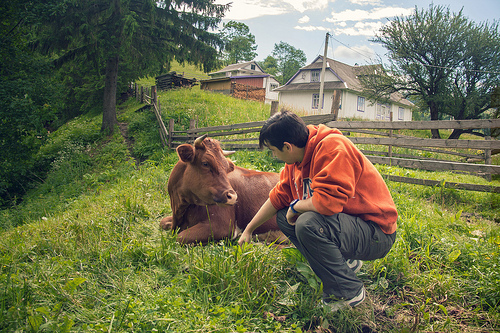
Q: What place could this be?
A: It is a yard.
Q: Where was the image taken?
A: It was taken at the yard.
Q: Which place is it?
A: It is a yard.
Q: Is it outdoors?
A: Yes, it is outdoors.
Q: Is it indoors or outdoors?
A: It is outdoors.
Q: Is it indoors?
A: No, it is outdoors.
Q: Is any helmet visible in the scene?
A: No, there are no helmets.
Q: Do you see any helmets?
A: No, there are no helmets.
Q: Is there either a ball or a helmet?
A: No, there are no helmets or balls.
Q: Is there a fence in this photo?
A: Yes, there is a fence.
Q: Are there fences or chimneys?
A: Yes, there is a fence.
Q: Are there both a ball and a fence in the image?
A: No, there is a fence but no balls.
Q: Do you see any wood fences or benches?
A: Yes, there is a wood fence.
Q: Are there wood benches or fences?
A: Yes, there is a wood fence.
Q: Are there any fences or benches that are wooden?
A: Yes, the fence is wooden.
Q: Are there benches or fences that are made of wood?
A: Yes, the fence is made of wood.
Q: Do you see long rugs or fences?
A: Yes, there is a long fence.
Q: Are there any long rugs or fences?
A: Yes, there is a long fence.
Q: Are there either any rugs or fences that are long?
A: Yes, the fence is long.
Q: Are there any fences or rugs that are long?
A: Yes, the fence is long.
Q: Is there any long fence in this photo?
A: Yes, there is a long fence.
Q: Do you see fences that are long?
A: Yes, there is a fence that is long.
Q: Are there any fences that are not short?
A: Yes, there is a long fence.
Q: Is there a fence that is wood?
A: Yes, there is a wood fence.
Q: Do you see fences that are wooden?
A: Yes, there is a fence that is wooden.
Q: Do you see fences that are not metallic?
A: Yes, there is a wooden fence.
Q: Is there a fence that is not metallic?
A: Yes, there is a wooden fence.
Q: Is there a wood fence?
A: Yes, there is a fence that is made of wood.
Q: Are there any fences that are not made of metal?
A: Yes, there is a fence that is made of wood.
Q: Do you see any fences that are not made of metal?
A: Yes, there is a fence that is made of wood.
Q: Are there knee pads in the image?
A: No, there are no knee pads.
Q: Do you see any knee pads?
A: No, there are no knee pads.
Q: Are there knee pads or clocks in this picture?
A: No, there are no knee pads or clocks.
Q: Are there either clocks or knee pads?
A: No, there are no knee pads or clocks.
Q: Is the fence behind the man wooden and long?
A: Yes, the fence is wooden and long.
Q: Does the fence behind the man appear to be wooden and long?
A: Yes, the fence is wooden and long.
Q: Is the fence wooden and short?
A: No, the fence is wooden but long.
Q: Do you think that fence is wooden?
A: Yes, the fence is wooden.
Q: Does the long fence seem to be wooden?
A: Yes, the fence is wooden.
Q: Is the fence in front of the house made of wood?
A: Yes, the fence is made of wood.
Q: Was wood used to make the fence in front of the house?
A: Yes, the fence is made of wood.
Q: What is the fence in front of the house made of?
A: The fence is made of wood.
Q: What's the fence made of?
A: The fence is made of wood.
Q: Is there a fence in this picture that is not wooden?
A: No, there is a fence but it is wooden.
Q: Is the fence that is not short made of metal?
A: No, the fence is made of wood.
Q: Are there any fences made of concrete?
A: No, there is a fence but it is made of wood.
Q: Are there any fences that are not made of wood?
A: No, there is a fence but it is made of wood.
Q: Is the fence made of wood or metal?
A: The fence is made of wood.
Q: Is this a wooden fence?
A: Yes, this is a wooden fence.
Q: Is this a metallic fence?
A: No, this is a wooden fence.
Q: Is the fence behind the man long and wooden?
A: Yes, the fence is long and wooden.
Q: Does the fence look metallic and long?
A: No, the fence is long but wooden.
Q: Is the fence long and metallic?
A: No, the fence is long but wooden.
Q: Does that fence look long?
A: Yes, the fence is long.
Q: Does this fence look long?
A: Yes, the fence is long.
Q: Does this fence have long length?
A: Yes, the fence is long.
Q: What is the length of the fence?
A: The fence is long.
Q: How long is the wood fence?
A: The fence is long.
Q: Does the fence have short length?
A: No, the fence is long.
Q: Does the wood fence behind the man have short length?
A: No, the fence is long.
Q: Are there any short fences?
A: No, there is a fence but it is long.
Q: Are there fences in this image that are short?
A: No, there is a fence but it is long.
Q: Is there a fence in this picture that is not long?
A: No, there is a fence but it is long.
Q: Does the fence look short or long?
A: The fence is long.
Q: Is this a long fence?
A: Yes, this is a long fence.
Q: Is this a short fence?
A: No, this is a long fence.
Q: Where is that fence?
A: The fence is on the hill.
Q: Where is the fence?
A: The fence is on the hill.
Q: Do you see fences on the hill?
A: Yes, there is a fence on the hill.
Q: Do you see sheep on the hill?
A: No, there is a fence on the hill.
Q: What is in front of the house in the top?
A: The fence is in front of the house.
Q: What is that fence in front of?
A: The fence is in front of the house.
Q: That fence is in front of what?
A: The fence is in front of the house.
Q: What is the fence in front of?
A: The fence is in front of the house.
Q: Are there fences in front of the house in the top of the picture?
A: Yes, there is a fence in front of the house.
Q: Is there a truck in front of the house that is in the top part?
A: No, there is a fence in front of the house.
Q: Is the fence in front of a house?
A: Yes, the fence is in front of a house.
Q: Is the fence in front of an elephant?
A: No, the fence is in front of a house.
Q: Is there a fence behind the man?
A: Yes, there is a fence behind the man.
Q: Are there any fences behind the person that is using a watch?
A: Yes, there is a fence behind the man.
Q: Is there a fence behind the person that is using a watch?
A: Yes, there is a fence behind the man.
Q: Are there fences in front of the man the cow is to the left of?
A: No, the fence is behind the man.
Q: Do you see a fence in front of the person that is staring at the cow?
A: No, the fence is behind the man.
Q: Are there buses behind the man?
A: No, there is a fence behind the man.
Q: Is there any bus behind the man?
A: No, there is a fence behind the man.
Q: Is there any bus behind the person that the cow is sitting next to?
A: No, there is a fence behind the man.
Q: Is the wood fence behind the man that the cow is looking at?
A: Yes, the fence is behind the man.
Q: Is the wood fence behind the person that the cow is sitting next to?
A: Yes, the fence is behind the man.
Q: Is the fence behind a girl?
A: No, the fence is behind the man.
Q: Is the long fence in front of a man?
A: No, the fence is behind a man.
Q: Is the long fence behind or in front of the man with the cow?
A: The fence is behind the man.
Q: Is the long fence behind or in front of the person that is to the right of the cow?
A: The fence is behind the man.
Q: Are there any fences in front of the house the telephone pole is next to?
A: Yes, there is a fence in front of the house.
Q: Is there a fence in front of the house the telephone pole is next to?
A: Yes, there is a fence in front of the house.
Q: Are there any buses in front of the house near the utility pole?
A: No, there is a fence in front of the house.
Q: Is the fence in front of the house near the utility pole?
A: Yes, the fence is in front of the house.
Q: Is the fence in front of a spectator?
A: No, the fence is in front of the house.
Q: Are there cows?
A: Yes, there is a cow.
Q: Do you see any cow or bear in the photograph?
A: Yes, there is a cow.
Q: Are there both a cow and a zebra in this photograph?
A: No, there is a cow but no zebras.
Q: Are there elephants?
A: No, there are no elephants.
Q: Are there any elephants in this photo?
A: No, there are no elephants.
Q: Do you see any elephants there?
A: No, there are no elephants.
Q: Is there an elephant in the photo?
A: No, there are no elephants.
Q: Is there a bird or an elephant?
A: No, there are no elephants or birds.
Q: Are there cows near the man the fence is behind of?
A: Yes, there is a cow near the man.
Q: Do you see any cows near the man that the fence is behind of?
A: Yes, there is a cow near the man.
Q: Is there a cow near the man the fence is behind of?
A: Yes, there is a cow near the man.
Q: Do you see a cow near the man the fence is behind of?
A: Yes, there is a cow near the man.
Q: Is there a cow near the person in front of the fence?
A: Yes, there is a cow near the man.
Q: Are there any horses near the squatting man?
A: No, there is a cow near the man.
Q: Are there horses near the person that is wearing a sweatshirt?
A: No, there is a cow near the man.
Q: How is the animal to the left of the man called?
A: The animal is a cow.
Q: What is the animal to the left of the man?
A: The animal is a cow.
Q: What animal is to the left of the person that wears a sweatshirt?
A: The animal is a cow.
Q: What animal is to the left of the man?
A: The animal is a cow.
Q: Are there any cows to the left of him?
A: Yes, there is a cow to the left of the man.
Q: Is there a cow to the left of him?
A: Yes, there is a cow to the left of the man.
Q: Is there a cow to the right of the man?
A: No, the cow is to the left of the man.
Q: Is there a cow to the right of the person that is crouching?
A: No, the cow is to the left of the man.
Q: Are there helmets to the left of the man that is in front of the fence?
A: No, there is a cow to the left of the man.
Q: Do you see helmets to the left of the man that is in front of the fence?
A: No, there is a cow to the left of the man.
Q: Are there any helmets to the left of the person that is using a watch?
A: No, there is a cow to the left of the man.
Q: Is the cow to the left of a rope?
A: No, the cow is to the left of the man.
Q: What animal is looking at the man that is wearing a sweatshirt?
A: The cow is looking at the man.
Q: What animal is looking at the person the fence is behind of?
A: The cow is looking at the man.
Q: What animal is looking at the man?
A: The cow is looking at the man.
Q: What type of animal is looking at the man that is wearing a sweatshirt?
A: The animal is a cow.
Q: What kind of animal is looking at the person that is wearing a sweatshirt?
A: The animal is a cow.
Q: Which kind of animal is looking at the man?
A: The animal is a cow.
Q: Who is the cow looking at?
A: The cow is looking at the man.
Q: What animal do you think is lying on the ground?
A: The cow is lying on the ground.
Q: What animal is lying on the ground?
A: The cow is lying on the ground.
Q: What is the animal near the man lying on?
A: The cow is lying on the ground.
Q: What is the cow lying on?
A: The cow is lying on the ground.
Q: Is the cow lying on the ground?
A: Yes, the cow is lying on the ground.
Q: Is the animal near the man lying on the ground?
A: Yes, the cow is lying on the ground.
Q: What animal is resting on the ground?
A: The cow is resting on the ground.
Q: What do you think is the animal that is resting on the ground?
A: The animal is a cow.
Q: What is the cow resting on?
A: The cow is resting on the ground.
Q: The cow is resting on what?
A: The cow is resting on the ground.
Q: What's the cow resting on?
A: The cow is resting on the ground.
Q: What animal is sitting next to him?
A: The cow is sitting next to the man.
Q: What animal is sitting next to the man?
A: The cow is sitting next to the man.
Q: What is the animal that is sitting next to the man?
A: The animal is a cow.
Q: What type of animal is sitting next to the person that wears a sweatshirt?
A: The animal is a cow.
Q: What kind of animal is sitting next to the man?
A: The animal is a cow.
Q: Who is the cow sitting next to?
A: The cow is sitting next to the man.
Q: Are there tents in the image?
A: No, there are no tents.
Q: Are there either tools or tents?
A: No, there are no tents or tools.